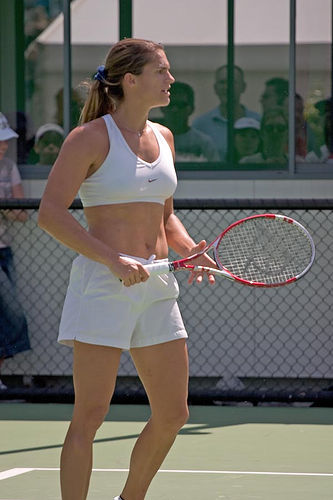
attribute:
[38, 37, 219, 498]
girl — white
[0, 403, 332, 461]
shadow — falling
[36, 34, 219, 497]
lady — light skinned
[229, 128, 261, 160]
ground — Playing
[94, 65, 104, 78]
bow — blue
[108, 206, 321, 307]
racket — white, red, silver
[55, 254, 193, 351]
short — white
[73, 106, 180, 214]
sports bra — white, black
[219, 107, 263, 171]
girl — beautiful, young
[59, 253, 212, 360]
shorts — white